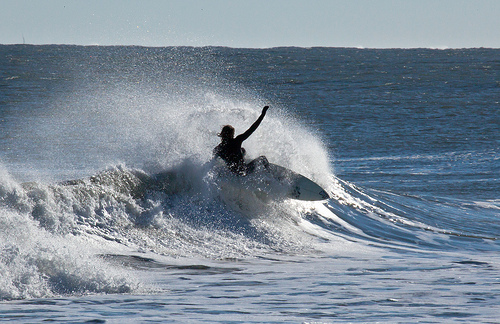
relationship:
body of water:
[334, 78, 445, 140] [11, 48, 108, 89]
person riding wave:
[194, 111, 288, 189] [95, 192, 199, 258]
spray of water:
[80, 112, 161, 152] [11, 48, 108, 89]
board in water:
[242, 159, 331, 202] [11, 48, 108, 89]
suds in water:
[190, 184, 245, 243] [11, 48, 108, 89]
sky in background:
[280, 4, 366, 27] [256, 17, 399, 71]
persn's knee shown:
[194, 111, 288, 189] [219, 131, 317, 200]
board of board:
[242, 159, 331, 202] [277, 127, 331, 244]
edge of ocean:
[291, 25, 461, 103] [0, 46, 500, 324]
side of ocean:
[15, 51, 149, 116] [0, 46, 500, 324]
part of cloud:
[320, 10, 407, 41] [293, 3, 427, 37]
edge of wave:
[291, 25, 461, 103] [95, 192, 199, 258]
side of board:
[15, 51, 149, 116] [277, 127, 331, 244]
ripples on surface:
[91, 158, 189, 211] [119, 178, 189, 230]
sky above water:
[280, 4, 366, 27] [11, 48, 108, 89]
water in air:
[11, 48, 108, 89] [252, 6, 332, 42]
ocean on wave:
[0, 46, 500, 324] [95, 192, 199, 258]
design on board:
[280, 177, 339, 202] [242, 159, 331, 202]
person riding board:
[211, 105, 270, 175] [242, 159, 331, 202]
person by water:
[211, 105, 270, 175] [11, 48, 108, 89]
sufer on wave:
[200, 126, 290, 174] [95, 192, 199, 258]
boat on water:
[17, 30, 40, 58] [11, 48, 108, 89]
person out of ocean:
[194, 111, 288, 189] [373, 66, 494, 152]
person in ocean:
[194, 111, 288, 189] [373, 66, 494, 152]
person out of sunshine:
[194, 111, 288, 189] [11, 4, 151, 50]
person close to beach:
[194, 111, 288, 189] [358, 246, 462, 304]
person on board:
[194, 111, 288, 189] [242, 159, 331, 202]